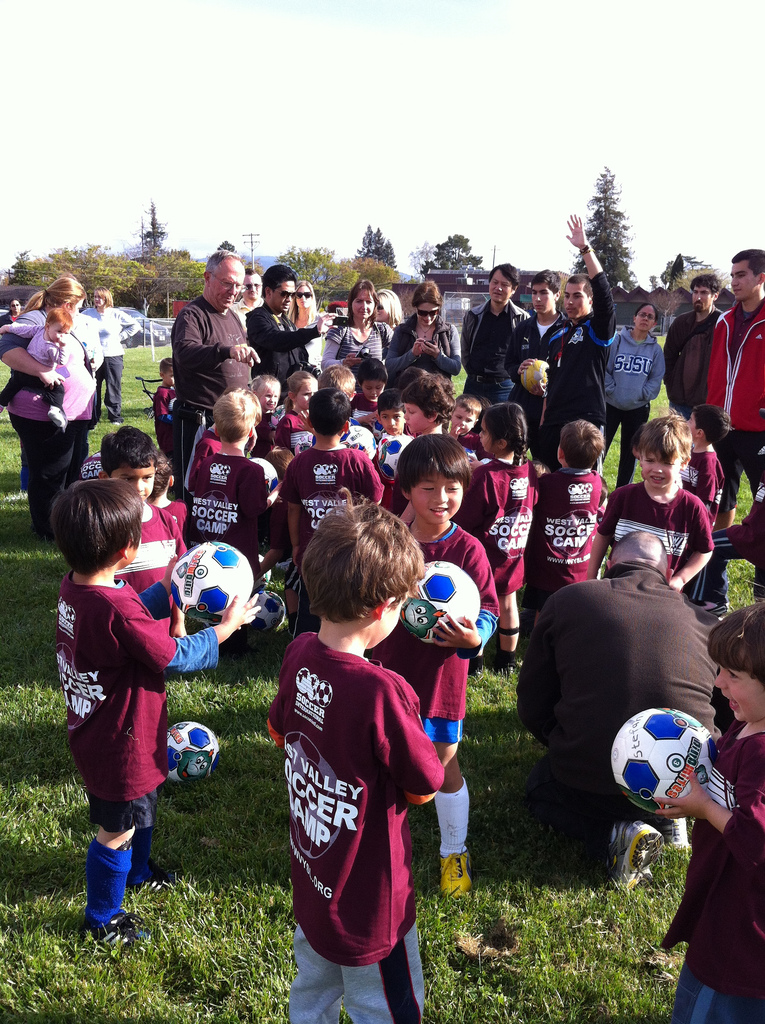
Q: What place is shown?
A: It is a field.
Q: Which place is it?
A: It is a field.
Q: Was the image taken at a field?
A: Yes, it was taken in a field.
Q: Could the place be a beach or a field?
A: It is a field.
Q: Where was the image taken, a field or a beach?
A: It was taken at a field.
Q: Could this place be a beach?
A: No, it is a field.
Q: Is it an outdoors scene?
A: Yes, it is outdoors.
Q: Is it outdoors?
A: Yes, it is outdoors.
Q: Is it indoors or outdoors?
A: It is outdoors.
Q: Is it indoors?
A: No, it is outdoors.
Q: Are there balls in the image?
A: Yes, there is a ball.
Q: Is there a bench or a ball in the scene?
A: Yes, there is a ball.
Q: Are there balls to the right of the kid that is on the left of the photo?
A: Yes, there is a ball to the right of the kid.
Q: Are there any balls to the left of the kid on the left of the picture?
A: No, the ball is to the right of the kid.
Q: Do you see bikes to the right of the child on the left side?
A: No, there is a ball to the right of the kid.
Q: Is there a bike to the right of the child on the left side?
A: No, there is a ball to the right of the kid.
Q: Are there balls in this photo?
A: Yes, there is a ball.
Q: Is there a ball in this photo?
A: Yes, there is a ball.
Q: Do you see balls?
A: Yes, there is a ball.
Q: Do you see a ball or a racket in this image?
A: Yes, there is a ball.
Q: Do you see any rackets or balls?
A: Yes, there is a ball.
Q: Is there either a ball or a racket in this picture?
A: Yes, there is a ball.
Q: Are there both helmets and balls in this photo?
A: No, there is a ball but no helmets.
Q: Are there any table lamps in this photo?
A: No, there are no table lamps.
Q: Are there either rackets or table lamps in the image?
A: No, there are no table lamps or rackets.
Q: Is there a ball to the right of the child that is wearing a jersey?
A: Yes, there is a ball to the right of the kid.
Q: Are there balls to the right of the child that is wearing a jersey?
A: Yes, there is a ball to the right of the kid.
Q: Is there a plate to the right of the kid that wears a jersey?
A: No, there is a ball to the right of the child.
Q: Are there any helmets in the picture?
A: No, there are no helmets.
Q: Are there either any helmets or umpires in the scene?
A: No, there are no helmets or umpires.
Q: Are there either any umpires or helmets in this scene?
A: No, there are no helmets or umpires.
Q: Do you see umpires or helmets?
A: No, there are no helmets or umpires.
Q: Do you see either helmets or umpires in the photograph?
A: No, there are no helmets or umpires.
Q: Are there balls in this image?
A: Yes, there is a ball.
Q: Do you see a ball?
A: Yes, there is a ball.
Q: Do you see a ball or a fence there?
A: Yes, there is a ball.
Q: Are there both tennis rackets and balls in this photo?
A: No, there is a ball but no rackets.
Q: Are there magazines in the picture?
A: No, there are no magazines.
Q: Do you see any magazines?
A: No, there are no magazines.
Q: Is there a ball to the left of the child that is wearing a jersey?
A: Yes, there is a ball to the left of the kid.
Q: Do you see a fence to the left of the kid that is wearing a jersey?
A: No, there is a ball to the left of the child.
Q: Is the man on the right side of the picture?
A: Yes, the man is on the right of the image.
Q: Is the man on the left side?
A: No, the man is on the right of the image.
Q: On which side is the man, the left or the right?
A: The man is on the right of the image.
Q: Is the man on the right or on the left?
A: The man is on the right of the image.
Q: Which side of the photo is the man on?
A: The man is on the right of the image.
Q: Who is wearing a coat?
A: The man is wearing a coat.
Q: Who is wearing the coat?
A: The man is wearing a coat.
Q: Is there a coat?
A: Yes, there is a coat.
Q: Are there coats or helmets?
A: Yes, there is a coat.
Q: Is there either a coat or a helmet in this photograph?
A: Yes, there is a coat.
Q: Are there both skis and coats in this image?
A: No, there is a coat but no skis.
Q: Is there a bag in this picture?
A: No, there are no bags.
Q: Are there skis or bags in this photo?
A: No, there are no bags or skis.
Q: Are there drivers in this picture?
A: No, there are no drivers.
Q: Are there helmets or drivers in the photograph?
A: No, there are no drivers or helmets.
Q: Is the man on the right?
A: Yes, the man is on the right of the image.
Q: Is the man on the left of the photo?
A: No, the man is on the right of the image.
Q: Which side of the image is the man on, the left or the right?
A: The man is on the right of the image.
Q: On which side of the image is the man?
A: The man is on the right of the image.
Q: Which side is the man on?
A: The man is on the right of the image.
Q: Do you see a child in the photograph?
A: Yes, there is a child.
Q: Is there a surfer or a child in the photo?
A: Yes, there is a child.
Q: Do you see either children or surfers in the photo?
A: Yes, there is a child.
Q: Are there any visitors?
A: No, there are no visitors.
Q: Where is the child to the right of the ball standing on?
A: The kid is standing on the field.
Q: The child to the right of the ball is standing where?
A: The kid is standing on the field.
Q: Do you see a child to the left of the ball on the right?
A: Yes, there is a child to the left of the ball.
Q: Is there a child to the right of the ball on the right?
A: No, the child is to the left of the ball.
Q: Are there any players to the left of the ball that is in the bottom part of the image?
A: No, there is a child to the left of the ball.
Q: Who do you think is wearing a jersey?
A: The child is wearing a jersey.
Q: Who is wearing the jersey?
A: The child is wearing a jersey.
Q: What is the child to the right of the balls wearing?
A: The child is wearing a jersey.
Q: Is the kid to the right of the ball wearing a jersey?
A: Yes, the kid is wearing a jersey.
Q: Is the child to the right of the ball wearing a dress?
A: No, the kid is wearing a jersey.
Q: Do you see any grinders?
A: No, there are no grinders.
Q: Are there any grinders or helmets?
A: No, there are no grinders or helmets.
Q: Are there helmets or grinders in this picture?
A: No, there are no grinders or helmets.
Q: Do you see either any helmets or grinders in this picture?
A: No, there are no grinders or helmets.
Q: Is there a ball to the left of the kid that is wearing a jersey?
A: Yes, there are balls to the left of the child.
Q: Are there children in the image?
A: Yes, there is a child.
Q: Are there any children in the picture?
A: Yes, there is a child.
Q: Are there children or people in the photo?
A: Yes, there is a child.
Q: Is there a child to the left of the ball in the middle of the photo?
A: Yes, there is a child to the left of the ball.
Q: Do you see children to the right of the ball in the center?
A: No, the child is to the left of the ball.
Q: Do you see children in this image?
A: Yes, there is a child.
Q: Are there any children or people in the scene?
A: Yes, there is a child.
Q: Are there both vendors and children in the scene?
A: No, there is a child but no vendors.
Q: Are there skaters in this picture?
A: No, there are no skaters.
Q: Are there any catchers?
A: No, there are no catchers.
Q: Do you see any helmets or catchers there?
A: No, there are no catchers or helmets.